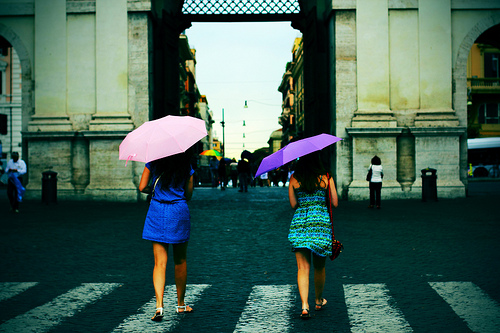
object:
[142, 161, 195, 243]
dress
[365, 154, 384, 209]
woman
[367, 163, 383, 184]
shirt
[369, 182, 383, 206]
pants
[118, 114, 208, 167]
pink umbrella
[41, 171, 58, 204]
trashcans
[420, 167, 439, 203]
receptacle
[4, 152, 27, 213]
man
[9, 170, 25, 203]
blue jeans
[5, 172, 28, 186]
bench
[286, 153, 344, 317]
person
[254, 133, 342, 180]
umbrella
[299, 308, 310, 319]
sandal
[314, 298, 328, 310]
sandal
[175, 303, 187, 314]
sandal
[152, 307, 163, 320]
sandal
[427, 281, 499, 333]
lines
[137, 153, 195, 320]
person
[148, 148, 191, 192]
hair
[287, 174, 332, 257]
dress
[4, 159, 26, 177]
coat